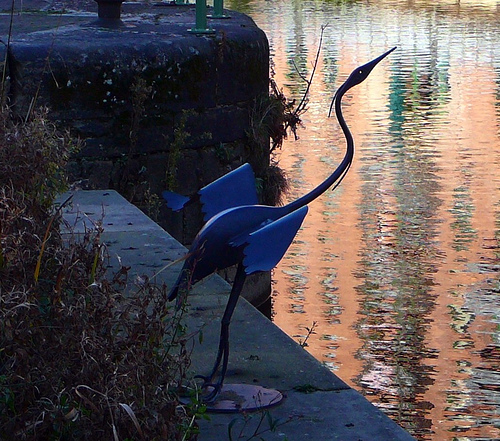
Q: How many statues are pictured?
A: One.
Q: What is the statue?
A: A crane.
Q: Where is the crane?
A: On the sidewalk.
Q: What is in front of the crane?
A: Water.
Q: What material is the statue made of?
A: Metal.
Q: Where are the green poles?
A: To the left of the crane statue.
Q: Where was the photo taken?
A: On a concrete sidewalk by the lake.